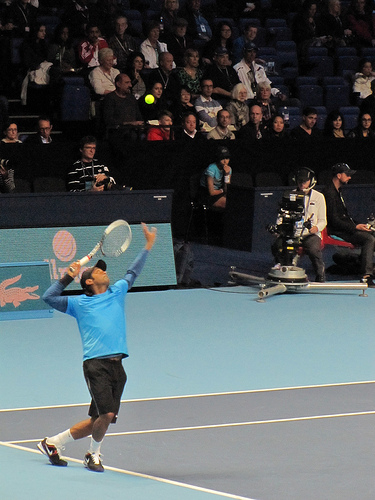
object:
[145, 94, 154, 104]
tennis ball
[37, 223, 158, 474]
tennis player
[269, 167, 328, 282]
person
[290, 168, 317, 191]
headset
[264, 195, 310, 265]
camera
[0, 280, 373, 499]
tennis court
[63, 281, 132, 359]
shirt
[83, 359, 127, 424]
shorts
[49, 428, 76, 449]
sock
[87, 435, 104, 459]
sock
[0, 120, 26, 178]
viewers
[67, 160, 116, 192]
sweater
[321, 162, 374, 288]
man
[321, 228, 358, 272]
chair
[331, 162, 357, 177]
cap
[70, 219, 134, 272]
racket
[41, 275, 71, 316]
arm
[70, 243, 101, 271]
handle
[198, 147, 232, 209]
viewer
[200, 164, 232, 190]
shirt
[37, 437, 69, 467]
shoe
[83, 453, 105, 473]
shoe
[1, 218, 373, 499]
tennis match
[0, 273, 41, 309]
logo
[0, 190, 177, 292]
wall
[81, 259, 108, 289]
cap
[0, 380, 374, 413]
line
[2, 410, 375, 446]
line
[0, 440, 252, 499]
line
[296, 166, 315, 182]
cap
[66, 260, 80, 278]
hand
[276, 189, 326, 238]
shirt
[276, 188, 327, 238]
jacket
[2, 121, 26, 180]
woman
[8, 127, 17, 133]
glasses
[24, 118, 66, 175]
man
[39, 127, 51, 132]
glasses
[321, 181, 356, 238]
jacket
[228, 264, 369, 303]
support